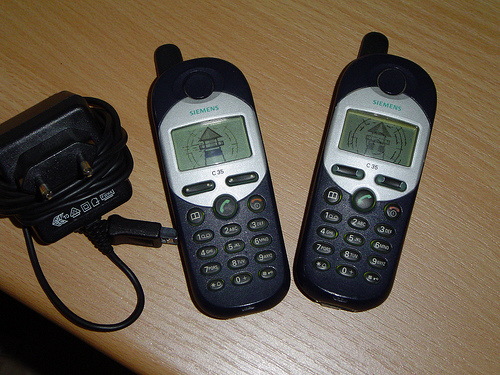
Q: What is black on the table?
A: Cell phone.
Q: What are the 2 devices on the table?
A: Cell phones.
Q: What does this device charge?
A: Cell phone.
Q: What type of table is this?
A: Wood.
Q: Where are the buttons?
A: Cell phone.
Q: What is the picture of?
A: 2 cell phones.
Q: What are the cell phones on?
A: The table.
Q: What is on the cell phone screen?
A: A triangle shape.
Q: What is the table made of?
A: Wood.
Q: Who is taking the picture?
A: A photographer.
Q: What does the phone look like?
A: The phone is black.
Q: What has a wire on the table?
A: A charger.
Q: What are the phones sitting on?
A: The table.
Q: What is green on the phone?
A: The talk button.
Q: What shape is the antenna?
A: Round.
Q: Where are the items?
A: On table.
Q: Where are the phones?
A: Next to each other.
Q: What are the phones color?
A: Black/silver.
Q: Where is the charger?
A: Left of phone.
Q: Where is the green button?
A: Middle of phone.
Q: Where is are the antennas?
A: Left of phone.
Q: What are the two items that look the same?
A: Phones.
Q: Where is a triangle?
A: Phone screen.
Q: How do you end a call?
A: Button with red phone.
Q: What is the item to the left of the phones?
A: Charger.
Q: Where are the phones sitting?
A: Table.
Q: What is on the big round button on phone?
A: Green phone.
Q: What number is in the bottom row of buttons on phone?
A: Zero.